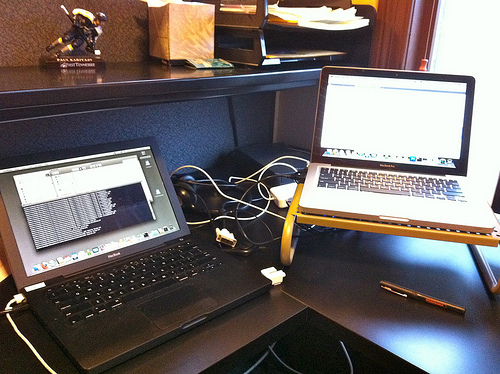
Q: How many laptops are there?
A: 2.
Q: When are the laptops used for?
A: For work.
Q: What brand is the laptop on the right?
A: Apple.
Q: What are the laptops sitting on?
A: Desk.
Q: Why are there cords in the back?
A: To power the laptops.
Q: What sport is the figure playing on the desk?
A: Hockey.